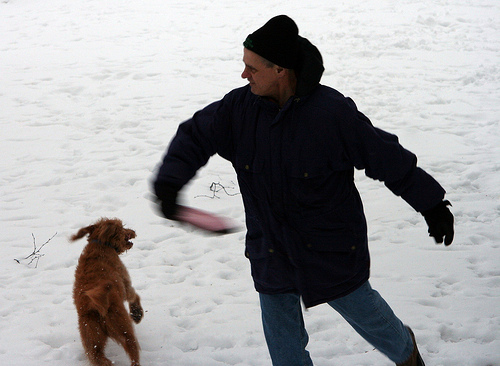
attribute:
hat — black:
[242, 14, 300, 69]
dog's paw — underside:
[126, 294, 143, 325]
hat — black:
[237, 5, 323, 70]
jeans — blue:
[252, 278, 428, 364]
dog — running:
[22, 185, 173, 363]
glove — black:
[402, 206, 465, 259]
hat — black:
[245, 10, 310, 82]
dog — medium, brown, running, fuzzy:
[68, 214, 148, 358]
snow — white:
[1, 0, 498, 361]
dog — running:
[72, 222, 143, 359]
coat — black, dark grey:
[151, 88, 441, 309]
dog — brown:
[64, 220, 151, 360]